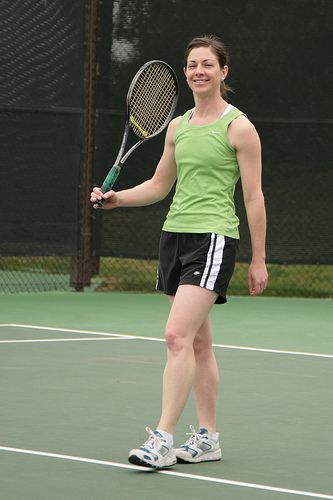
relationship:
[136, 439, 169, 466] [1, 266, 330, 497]
foot on ground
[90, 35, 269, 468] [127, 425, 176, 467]
woman wearing shoe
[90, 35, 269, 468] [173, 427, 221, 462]
woman wearing shoe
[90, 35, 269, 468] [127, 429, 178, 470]
woman wearing shoe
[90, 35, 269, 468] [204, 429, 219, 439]
woman wearing socks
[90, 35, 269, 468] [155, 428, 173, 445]
woman wearing socks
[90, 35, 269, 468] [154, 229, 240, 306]
woman wearing shorts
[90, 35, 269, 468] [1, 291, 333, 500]
woman on tennis court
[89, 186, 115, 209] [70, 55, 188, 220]
fingers wrapped around racket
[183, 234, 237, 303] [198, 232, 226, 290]
shorts have line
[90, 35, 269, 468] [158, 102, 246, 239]
woman wearing tank top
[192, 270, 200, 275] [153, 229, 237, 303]
logo on shorts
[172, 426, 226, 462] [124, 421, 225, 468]
shoe on feet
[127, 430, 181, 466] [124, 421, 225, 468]
shoe on feet